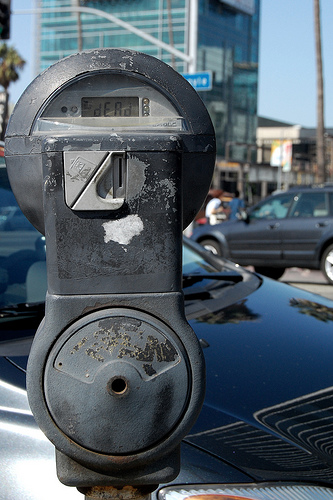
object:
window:
[161, 31, 184, 43]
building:
[28, 0, 263, 164]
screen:
[80, 94, 140, 117]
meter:
[3, 48, 216, 498]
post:
[77, 487, 159, 499]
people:
[205, 188, 225, 226]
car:
[186, 186, 333, 285]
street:
[246, 264, 333, 299]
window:
[219, 171, 238, 195]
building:
[215, 158, 316, 221]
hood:
[1, 271, 332, 498]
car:
[0, 156, 332, 498]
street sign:
[180, 71, 216, 90]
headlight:
[156, 481, 331, 499]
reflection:
[180, 368, 333, 493]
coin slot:
[118, 154, 124, 189]